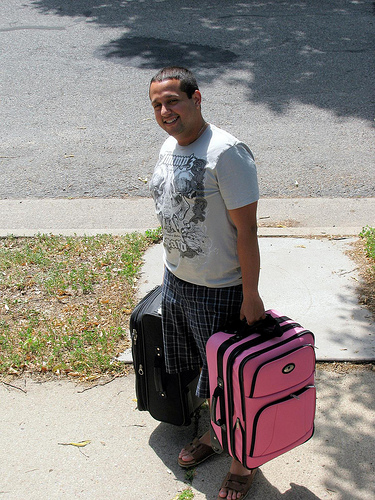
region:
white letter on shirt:
[159, 151, 172, 166]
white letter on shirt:
[165, 154, 173, 164]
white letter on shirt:
[171, 155, 179, 165]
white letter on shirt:
[179, 155, 184, 168]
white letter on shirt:
[177, 238, 187, 254]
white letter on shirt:
[174, 237, 182, 251]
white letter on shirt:
[169, 238, 175, 252]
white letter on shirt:
[187, 156, 197, 171]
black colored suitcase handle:
[208, 381, 221, 432]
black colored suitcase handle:
[150, 351, 164, 400]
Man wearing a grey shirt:
[148, 127, 256, 282]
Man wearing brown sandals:
[176, 439, 256, 499]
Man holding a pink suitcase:
[199, 315, 315, 470]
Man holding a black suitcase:
[126, 283, 204, 430]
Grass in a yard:
[0, 231, 146, 375]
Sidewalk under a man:
[2, 359, 373, 498]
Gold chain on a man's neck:
[194, 121, 210, 140]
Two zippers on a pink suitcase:
[284, 382, 315, 398]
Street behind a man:
[1, 1, 374, 195]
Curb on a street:
[2, 198, 373, 235]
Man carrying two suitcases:
[126, 63, 317, 498]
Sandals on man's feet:
[175, 427, 255, 498]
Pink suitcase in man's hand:
[206, 293, 317, 470]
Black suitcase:
[128, 277, 193, 427]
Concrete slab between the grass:
[120, 233, 373, 363]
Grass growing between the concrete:
[171, 467, 198, 499]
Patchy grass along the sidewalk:
[0, 233, 157, 384]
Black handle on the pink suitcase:
[210, 382, 222, 430]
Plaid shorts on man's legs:
[158, 268, 245, 399]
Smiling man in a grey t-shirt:
[143, 69, 261, 292]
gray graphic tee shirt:
[151, 138, 268, 293]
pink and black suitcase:
[198, 304, 319, 466]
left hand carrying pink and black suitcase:
[188, 295, 321, 470]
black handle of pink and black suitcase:
[210, 377, 239, 430]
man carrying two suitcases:
[116, 59, 326, 497]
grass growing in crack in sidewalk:
[171, 482, 207, 499]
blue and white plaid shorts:
[154, 266, 267, 398]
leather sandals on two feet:
[176, 435, 253, 498]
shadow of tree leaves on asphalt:
[39, 0, 370, 122]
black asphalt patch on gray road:
[92, 32, 237, 72]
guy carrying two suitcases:
[105, 53, 327, 498]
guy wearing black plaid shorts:
[131, 62, 291, 492]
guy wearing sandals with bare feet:
[125, 58, 279, 496]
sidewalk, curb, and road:
[267, 0, 372, 402]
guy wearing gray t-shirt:
[120, 46, 282, 272]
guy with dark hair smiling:
[121, 49, 316, 259]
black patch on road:
[69, 9, 371, 119]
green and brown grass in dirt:
[11, 232, 127, 396]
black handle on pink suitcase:
[198, 329, 353, 499]